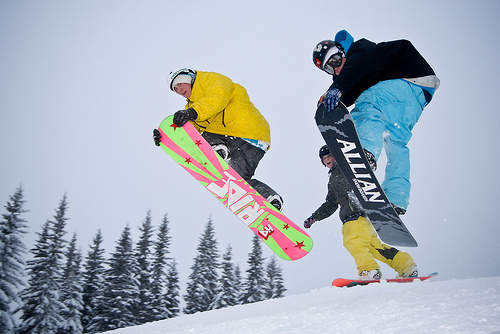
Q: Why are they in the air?
A: Jumping.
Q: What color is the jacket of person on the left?
A: Yellow.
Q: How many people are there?
A: Three.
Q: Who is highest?
A: Person in yellow jacket.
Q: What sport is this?
A: Snowboarding.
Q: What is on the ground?
A: Snow.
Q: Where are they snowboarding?
A: On a mountain.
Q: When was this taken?
A: During the day.